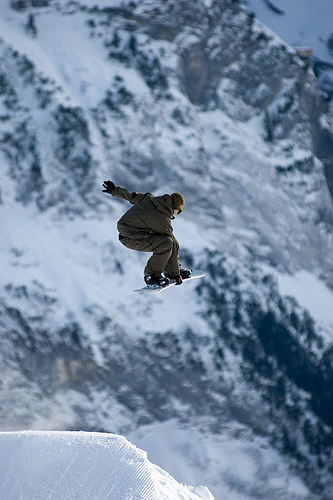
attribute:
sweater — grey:
[110, 182, 189, 259]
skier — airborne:
[100, 179, 191, 284]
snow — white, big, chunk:
[1, 428, 214, 499]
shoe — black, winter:
[142, 271, 170, 286]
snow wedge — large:
[1, 428, 214, 498]